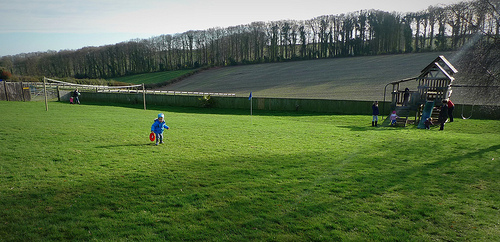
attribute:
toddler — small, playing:
[149, 114, 170, 145]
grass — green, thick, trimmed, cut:
[1, 98, 499, 241]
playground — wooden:
[383, 54, 457, 129]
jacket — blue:
[151, 118, 168, 135]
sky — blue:
[0, 0, 499, 47]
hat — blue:
[156, 113, 164, 119]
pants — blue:
[156, 132, 165, 143]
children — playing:
[70, 87, 454, 145]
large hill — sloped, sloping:
[91, 49, 498, 103]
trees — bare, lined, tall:
[0, 1, 499, 117]